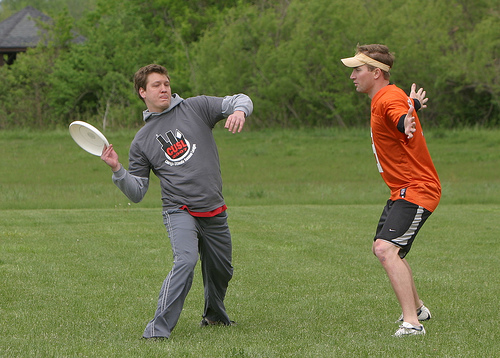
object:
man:
[100, 62, 256, 346]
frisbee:
[66, 118, 113, 159]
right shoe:
[393, 304, 433, 322]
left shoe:
[384, 320, 431, 341]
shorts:
[368, 193, 436, 260]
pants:
[142, 206, 235, 341]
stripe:
[163, 262, 179, 313]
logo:
[150, 126, 199, 166]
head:
[132, 62, 173, 110]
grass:
[0, 127, 500, 356]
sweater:
[110, 91, 257, 214]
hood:
[139, 91, 187, 122]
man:
[336, 40, 444, 337]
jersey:
[365, 81, 444, 214]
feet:
[135, 327, 177, 347]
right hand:
[97, 139, 122, 170]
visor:
[337, 48, 395, 75]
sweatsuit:
[110, 90, 256, 338]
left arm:
[191, 91, 255, 119]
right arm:
[119, 132, 154, 208]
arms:
[380, 89, 406, 135]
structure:
[0, 0, 94, 74]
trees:
[50, 0, 78, 52]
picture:
[0, 0, 499, 357]